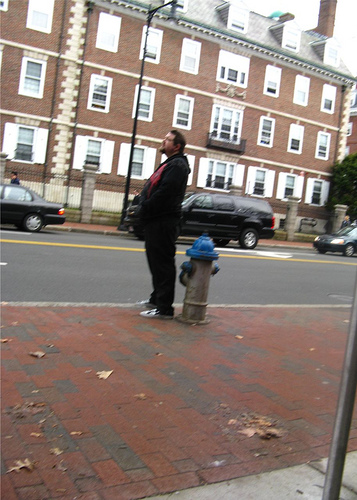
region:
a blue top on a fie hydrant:
[186, 226, 225, 261]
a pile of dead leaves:
[229, 390, 290, 439]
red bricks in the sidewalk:
[113, 398, 187, 464]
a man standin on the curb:
[120, 117, 183, 318]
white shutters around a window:
[267, 168, 287, 202]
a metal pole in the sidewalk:
[331, 354, 343, 498]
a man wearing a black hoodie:
[122, 129, 179, 309]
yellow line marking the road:
[32, 239, 114, 261]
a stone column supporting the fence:
[76, 171, 96, 226]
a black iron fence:
[39, 175, 75, 198]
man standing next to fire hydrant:
[137, 126, 223, 331]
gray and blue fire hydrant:
[181, 226, 221, 330]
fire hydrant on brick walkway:
[185, 237, 303, 390]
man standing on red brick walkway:
[132, 126, 184, 339]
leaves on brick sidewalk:
[9, 338, 295, 473]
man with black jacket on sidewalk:
[134, 124, 186, 322]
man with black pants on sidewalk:
[133, 129, 186, 328]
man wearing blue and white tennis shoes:
[133, 128, 186, 323]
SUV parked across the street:
[120, 185, 282, 249]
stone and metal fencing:
[42, 164, 114, 226]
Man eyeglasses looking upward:
[135, 125, 184, 334]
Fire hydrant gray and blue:
[178, 234, 224, 327]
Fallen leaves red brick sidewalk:
[7, 337, 148, 480]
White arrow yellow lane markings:
[228, 247, 356, 276]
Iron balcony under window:
[205, 100, 249, 159]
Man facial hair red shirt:
[143, 127, 190, 191]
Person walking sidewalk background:
[5, 167, 28, 192]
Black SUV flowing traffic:
[181, 186, 295, 256]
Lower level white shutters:
[243, 155, 334, 216]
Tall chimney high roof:
[307, 0, 340, 44]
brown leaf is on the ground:
[217, 400, 283, 450]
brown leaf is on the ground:
[218, 375, 300, 461]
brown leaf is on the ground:
[90, 358, 123, 386]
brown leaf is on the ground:
[239, 402, 290, 463]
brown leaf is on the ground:
[30, 420, 97, 488]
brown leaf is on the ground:
[23, 343, 49, 366]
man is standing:
[125, 129, 192, 320]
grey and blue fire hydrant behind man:
[175, 232, 220, 326]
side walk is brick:
[0, 300, 356, 497]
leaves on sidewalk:
[0, 319, 351, 474]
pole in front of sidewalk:
[321, 271, 356, 498]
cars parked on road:
[0, 182, 356, 256]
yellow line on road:
[0, 238, 356, 266]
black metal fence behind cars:
[4, 165, 338, 243]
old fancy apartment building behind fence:
[0, 0, 356, 235]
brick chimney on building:
[305, 0, 338, 37]